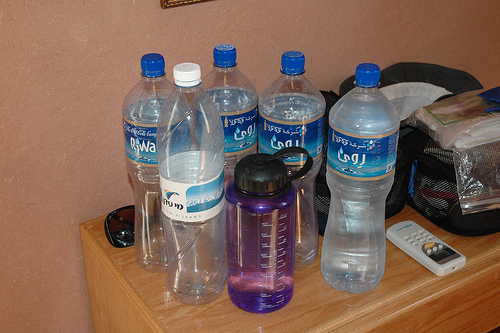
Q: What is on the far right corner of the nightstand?
A: Hat.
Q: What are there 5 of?
A: Bottles of water.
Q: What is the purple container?
A: Water bottle.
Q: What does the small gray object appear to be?
A: Remote control.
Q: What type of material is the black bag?
A: Mesh.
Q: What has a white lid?
A: Water bottle.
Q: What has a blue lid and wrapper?
A: Water bottle.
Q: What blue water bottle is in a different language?
A: Far left.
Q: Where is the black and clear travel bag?
A: On the table.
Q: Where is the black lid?
A: On the purple bottle.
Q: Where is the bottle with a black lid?
A: On the table.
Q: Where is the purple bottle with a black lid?
A: In front of the water bottles.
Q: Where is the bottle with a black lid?
A: On the wooden table.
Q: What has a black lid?
A: The purple bottle.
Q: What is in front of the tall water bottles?
A: A bottle with a black lid.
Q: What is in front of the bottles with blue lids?
A: A bottle with a black lid.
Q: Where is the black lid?
A: On the purple water bottle.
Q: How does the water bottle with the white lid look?
A: Empty.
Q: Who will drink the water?
A: Thirsty people.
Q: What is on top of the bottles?
A: Caps.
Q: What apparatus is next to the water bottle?
A: Remote.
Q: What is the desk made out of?
A: Wood.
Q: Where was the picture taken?
A: The picture was taken indoors.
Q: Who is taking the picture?
A: The owner of the water bottles.